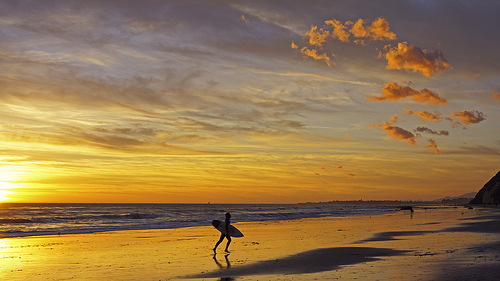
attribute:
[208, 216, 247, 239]
surf board — long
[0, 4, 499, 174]
sky — multicolored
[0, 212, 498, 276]
beach — sandy, twilight colored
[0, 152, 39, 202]
sun — setting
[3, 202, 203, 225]
ocean — blue, twilight darkened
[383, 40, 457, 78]
cloud — orange, fluffy, brown fluffy, tinted orange, formed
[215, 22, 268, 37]
sky — blue